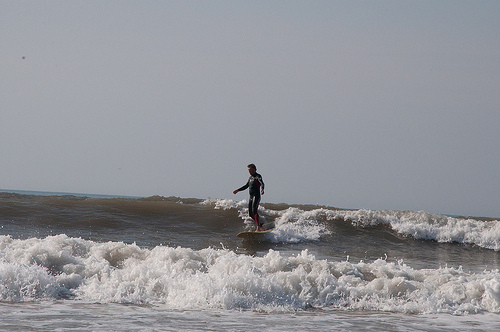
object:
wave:
[0, 233, 500, 318]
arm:
[256, 174, 264, 190]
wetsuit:
[236, 172, 265, 228]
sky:
[0, 0, 500, 220]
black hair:
[246, 163, 257, 171]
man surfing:
[231, 163, 276, 240]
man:
[232, 163, 264, 233]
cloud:
[0, 0, 500, 220]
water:
[0, 188, 500, 332]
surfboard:
[236, 220, 276, 242]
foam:
[0, 232, 500, 316]